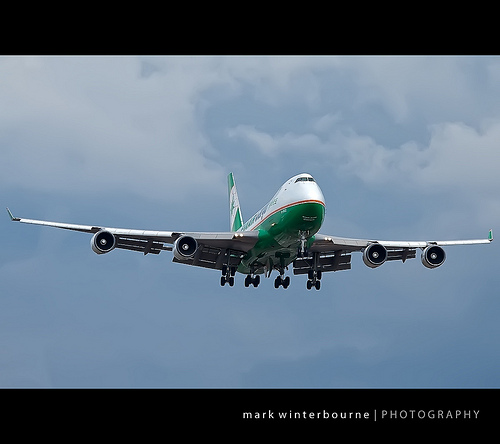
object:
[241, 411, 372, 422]
name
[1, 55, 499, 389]
skies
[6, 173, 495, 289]
jet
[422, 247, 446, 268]
engines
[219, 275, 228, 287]
wheels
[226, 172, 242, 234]
tail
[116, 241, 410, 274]
flaps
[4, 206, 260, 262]
wing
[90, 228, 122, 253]
engines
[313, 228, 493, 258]
wing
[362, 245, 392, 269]
engines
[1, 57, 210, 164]
clouds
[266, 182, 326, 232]
nose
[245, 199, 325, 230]
stripe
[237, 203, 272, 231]
name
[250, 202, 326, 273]
belly